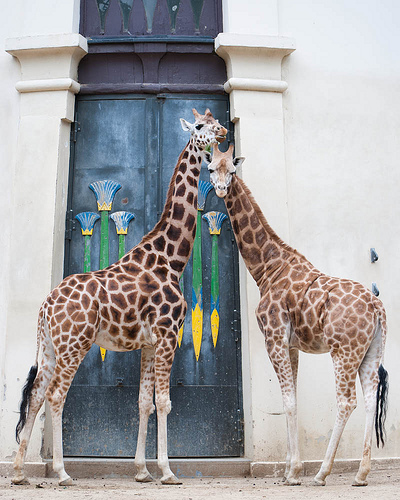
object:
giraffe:
[199, 142, 389, 489]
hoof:
[161, 475, 183, 485]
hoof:
[11, 476, 30, 485]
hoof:
[135, 473, 154, 482]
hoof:
[351, 479, 368, 485]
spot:
[243, 229, 253, 244]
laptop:
[146, 141, 202, 280]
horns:
[192, 108, 210, 117]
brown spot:
[255, 227, 267, 249]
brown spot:
[138, 272, 160, 294]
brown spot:
[239, 214, 249, 231]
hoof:
[283, 478, 301, 486]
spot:
[108, 279, 118, 291]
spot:
[143, 243, 152, 251]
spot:
[172, 203, 185, 220]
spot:
[186, 192, 194, 206]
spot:
[176, 175, 183, 185]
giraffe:
[9, 105, 230, 488]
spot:
[166, 224, 181, 241]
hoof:
[59, 477, 73, 486]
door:
[61, 0, 245, 460]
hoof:
[309, 478, 327, 486]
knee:
[283, 401, 297, 416]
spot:
[266, 259, 282, 278]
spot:
[177, 237, 191, 257]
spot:
[167, 243, 175, 257]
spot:
[144, 252, 157, 270]